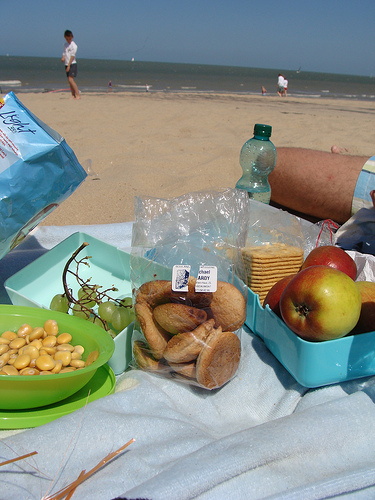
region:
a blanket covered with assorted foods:
[2, 212, 374, 491]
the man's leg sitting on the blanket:
[268, 146, 374, 219]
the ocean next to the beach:
[1, 55, 373, 92]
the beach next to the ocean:
[28, 96, 374, 227]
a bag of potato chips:
[2, 90, 88, 274]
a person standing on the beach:
[55, 29, 84, 93]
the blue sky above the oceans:
[2, 1, 373, 77]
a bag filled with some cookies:
[134, 200, 242, 394]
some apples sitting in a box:
[275, 243, 374, 335]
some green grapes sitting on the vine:
[51, 246, 129, 334]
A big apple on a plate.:
[278, 265, 361, 340]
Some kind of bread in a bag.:
[134, 280, 247, 389]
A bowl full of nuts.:
[2, 316, 95, 382]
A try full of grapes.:
[51, 283, 135, 337]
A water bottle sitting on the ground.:
[235, 124, 277, 203]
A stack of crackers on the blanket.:
[240, 244, 303, 304]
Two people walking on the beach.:
[277, 74, 288, 96]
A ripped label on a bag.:
[172, 264, 217, 293]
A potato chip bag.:
[1, 90, 86, 257]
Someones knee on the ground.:
[250, 148, 373, 224]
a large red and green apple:
[281, 265, 359, 340]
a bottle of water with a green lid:
[235, 120, 275, 207]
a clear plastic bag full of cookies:
[135, 188, 244, 392]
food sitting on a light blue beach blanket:
[1, 198, 373, 499]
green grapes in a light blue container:
[51, 241, 134, 333]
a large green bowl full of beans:
[1, 302, 112, 427]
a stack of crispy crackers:
[248, 243, 302, 309]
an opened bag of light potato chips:
[1, 91, 83, 277]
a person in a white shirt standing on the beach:
[61, 29, 83, 100]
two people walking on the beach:
[277, 73, 288, 96]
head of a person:
[62, 25, 77, 40]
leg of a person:
[253, 140, 371, 219]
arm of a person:
[71, 42, 82, 67]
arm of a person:
[62, 43, 71, 64]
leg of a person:
[66, 59, 91, 93]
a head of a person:
[59, 18, 84, 45]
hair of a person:
[66, 23, 77, 33]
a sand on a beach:
[122, 106, 207, 146]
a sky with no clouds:
[150, 2, 265, 40]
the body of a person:
[61, 40, 84, 75]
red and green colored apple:
[278, 266, 362, 339]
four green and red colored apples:
[261, 244, 374, 342]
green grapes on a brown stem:
[50, 241, 136, 339]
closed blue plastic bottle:
[235, 121, 276, 202]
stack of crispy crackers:
[237, 242, 306, 305]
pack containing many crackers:
[239, 235, 305, 307]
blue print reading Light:
[0, 108, 37, 142]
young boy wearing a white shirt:
[58, 27, 81, 98]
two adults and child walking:
[259, 71, 293, 98]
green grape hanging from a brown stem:
[49, 290, 73, 310]